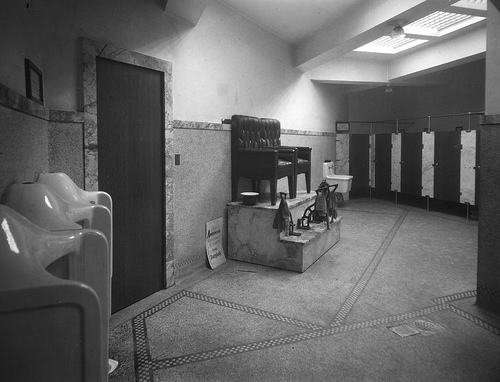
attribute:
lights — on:
[358, 2, 488, 58]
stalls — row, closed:
[348, 112, 480, 222]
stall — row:
[347, 131, 368, 184]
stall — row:
[374, 133, 391, 190]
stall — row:
[401, 129, 420, 194]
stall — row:
[434, 130, 458, 202]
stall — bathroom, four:
[368, 132, 377, 192]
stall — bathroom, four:
[388, 130, 401, 192]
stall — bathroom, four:
[420, 129, 434, 198]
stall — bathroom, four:
[459, 127, 477, 204]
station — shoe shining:
[229, 110, 339, 275]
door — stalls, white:
[459, 129, 475, 208]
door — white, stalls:
[419, 130, 436, 200]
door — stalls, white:
[388, 131, 402, 193]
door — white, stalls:
[365, 134, 374, 191]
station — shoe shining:
[163, 96, 451, 278]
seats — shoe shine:
[229, 114, 313, 204]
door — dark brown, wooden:
[94, 56, 166, 314]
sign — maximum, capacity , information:
[12, 60, 67, 115]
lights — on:
[343, 5, 475, 90]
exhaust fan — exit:
[355, 14, 498, 78]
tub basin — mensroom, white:
[321, 153, 353, 200]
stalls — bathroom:
[339, 127, 484, 201]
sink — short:
[317, 144, 366, 209]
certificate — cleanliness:
[16, 61, 61, 124]